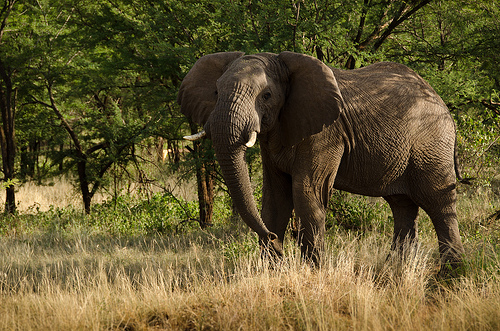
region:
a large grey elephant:
[178, 50, 476, 287]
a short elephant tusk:
[244, 129, 260, 147]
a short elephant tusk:
[183, 127, 208, 140]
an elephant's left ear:
[279, 48, 344, 153]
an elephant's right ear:
[178, 52, 245, 130]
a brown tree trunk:
[191, 142, 216, 224]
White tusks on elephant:
[181, 128, 261, 148]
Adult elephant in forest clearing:
[173, 50, 467, 298]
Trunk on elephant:
[214, 85, 276, 251]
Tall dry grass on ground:
[12, 176, 496, 329]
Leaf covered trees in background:
[2, 12, 497, 180]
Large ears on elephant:
[176, 50, 344, 142]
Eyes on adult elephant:
[211, 85, 272, 100]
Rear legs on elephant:
[390, 145, 464, 287]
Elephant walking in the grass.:
[182, 44, 482, 286]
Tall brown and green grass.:
[6, 260, 499, 329]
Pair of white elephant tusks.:
[174, 123, 264, 148]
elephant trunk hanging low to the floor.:
[202, 150, 304, 257]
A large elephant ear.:
[283, 45, 345, 157]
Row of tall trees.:
[5, 3, 190, 194]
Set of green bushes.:
[36, 195, 205, 233]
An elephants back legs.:
[376, 193, 483, 295]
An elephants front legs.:
[257, 171, 342, 274]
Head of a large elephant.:
[173, 55, 343, 244]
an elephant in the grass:
[175, 48, 477, 270]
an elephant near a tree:
[172, 48, 478, 283]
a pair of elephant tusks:
[182, 128, 258, 149]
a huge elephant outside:
[173, 48, 476, 279]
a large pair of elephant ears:
[171, 48, 344, 150]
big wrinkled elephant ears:
[173, 48, 345, 150]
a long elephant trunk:
[207, 78, 280, 245]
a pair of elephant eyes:
[211, 86, 271, 101]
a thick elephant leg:
[402, 159, 464, 277]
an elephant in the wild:
[177, 48, 479, 283]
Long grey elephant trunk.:
[205, 126, 278, 244]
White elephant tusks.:
[180, 126, 257, 148]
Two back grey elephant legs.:
[383, 189, 466, 285]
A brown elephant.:
[175, 52, 471, 272]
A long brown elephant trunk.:
[210, 117, 278, 244]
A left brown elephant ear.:
[277, 50, 344, 150]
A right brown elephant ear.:
[176, 52, 241, 127]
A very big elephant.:
[180, 52, 467, 281]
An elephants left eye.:
[262, 92, 271, 100]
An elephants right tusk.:
[182, 127, 209, 142]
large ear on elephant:
[288, 47, 335, 139]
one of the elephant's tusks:
[245, 129, 260, 155]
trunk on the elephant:
[219, 129, 260, 243]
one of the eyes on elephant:
[259, 89, 269, 101]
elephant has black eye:
[174, 48, 476, 286]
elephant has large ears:
[176, 50, 475, 292]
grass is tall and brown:
[1, 123, 498, 328]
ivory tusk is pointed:
[180, 130, 207, 141]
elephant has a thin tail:
[174, 52, 476, 288]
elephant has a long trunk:
[174, 51, 474, 290]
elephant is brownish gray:
[173, 48, 476, 287]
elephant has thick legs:
[176, 48, 475, 284]